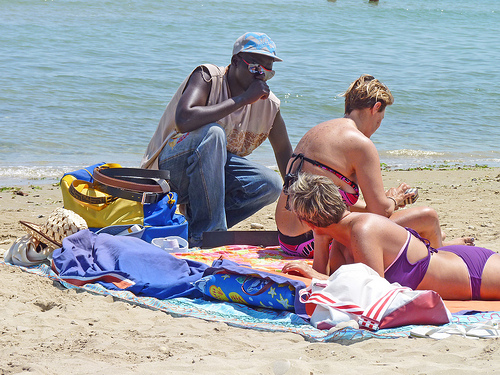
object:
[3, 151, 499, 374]
beach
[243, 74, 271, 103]
hand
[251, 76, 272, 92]
mouth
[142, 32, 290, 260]
man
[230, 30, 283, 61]
cap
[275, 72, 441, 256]
woman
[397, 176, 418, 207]
cell phone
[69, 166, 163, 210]
belts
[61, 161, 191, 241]
bag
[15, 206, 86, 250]
hat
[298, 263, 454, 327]
bag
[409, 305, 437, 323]
red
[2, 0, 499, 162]
water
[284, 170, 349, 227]
hair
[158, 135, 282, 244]
jeans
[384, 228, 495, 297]
bikini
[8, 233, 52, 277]
blanket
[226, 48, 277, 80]
sunglasses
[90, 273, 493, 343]
blanket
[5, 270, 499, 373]
sand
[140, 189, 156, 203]
buckle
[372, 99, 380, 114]
ear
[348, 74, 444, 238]
right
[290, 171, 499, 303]
woman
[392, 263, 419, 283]
purple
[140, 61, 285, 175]
sleeveless top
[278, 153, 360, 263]
bikini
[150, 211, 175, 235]
blue